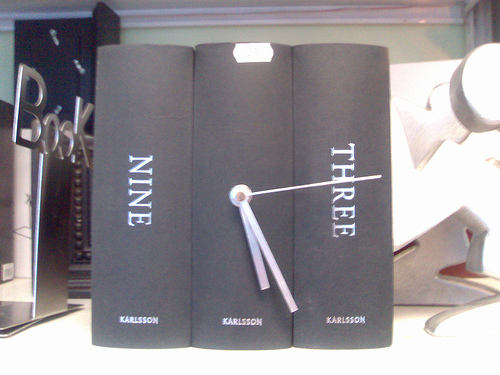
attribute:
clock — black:
[125, 99, 342, 265]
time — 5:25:
[193, 179, 285, 248]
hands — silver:
[203, 173, 308, 273]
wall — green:
[393, 27, 433, 49]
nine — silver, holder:
[119, 145, 169, 240]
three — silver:
[318, 140, 364, 240]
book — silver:
[113, 86, 222, 281]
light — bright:
[53, 28, 133, 85]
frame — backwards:
[5, 63, 98, 164]